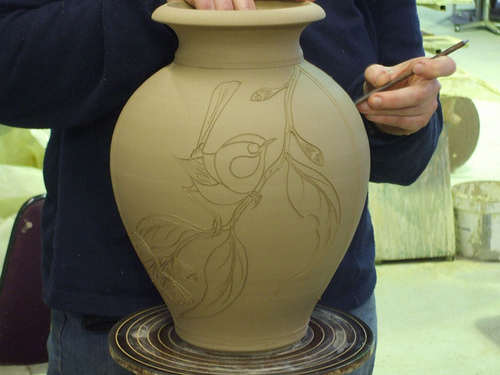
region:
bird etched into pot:
[172, 78, 287, 219]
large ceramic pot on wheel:
[99, 3, 394, 361]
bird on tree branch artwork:
[122, 66, 356, 341]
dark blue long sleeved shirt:
[7, 5, 464, 319]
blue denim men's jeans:
[32, 287, 392, 373]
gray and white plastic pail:
[447, 174, 499, 269]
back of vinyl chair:
[3, 186, 63, 365]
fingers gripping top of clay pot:
[110, 0, 340, 28]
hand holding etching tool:
[342, 33, 472, 148]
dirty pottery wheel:
[98, 292, 402, 374]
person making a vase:
[1, 0, 471, 374]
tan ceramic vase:
[98, 3, 386, 373]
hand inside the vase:
[190, 1, 260, 16]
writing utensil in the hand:
[353, 35, 478, 111]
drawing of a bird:
[181, 128, 284, 216]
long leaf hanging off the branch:
[176, 225, 272, 331]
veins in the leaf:
[211, 245, 247, 310]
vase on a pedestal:
[80, 2, 427, 372]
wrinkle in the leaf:
[81, 13, 112, 109]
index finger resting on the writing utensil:
[404, 54, 438, 82]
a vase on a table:
[104, 6, 450, 369]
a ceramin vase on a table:
[112, 4, 396, 374]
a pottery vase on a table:
[128, 5, 406, 371]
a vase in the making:
[89, 4, 400, 371]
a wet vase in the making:
[94, 13, 407, 350]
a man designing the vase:
[77, 6, 498, 343]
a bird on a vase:
[101, 28, 410, 368]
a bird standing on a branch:
[84, 27, 442, 373]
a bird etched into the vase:
[44, 14, 481, 369]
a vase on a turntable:
[107, 25, 401, 374]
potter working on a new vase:
[0, 10, 465, 365]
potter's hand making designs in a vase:
[343, 33, 467, 138]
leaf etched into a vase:
[274, 153, 341, 285]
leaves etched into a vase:
[130, 207, 250, 324]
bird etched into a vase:
[172, 75, 277, 207]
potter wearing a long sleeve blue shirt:
[11, 0, 446, 330]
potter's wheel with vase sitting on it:
[99, 300, 375, 371]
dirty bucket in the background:
[446, 175, 496, 265]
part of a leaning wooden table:
[352, 114, 462, 260]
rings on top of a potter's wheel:
[117, 305, 364, 367]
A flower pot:
[116, 11, 341, 348]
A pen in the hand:
[353, 36, 467, 106]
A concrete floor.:
[420, 295, 489, 363]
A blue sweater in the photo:
[48, 117, 115, 304]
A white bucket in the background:
[455, 181, 497, 267]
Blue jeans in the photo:
[47, 314, 114, 373]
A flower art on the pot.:
[151, 78, 341, 282]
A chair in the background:
[3, 192, 61, 347]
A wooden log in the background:
[375, 179, 459, 259]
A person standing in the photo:
[1, 1, 447, 373]